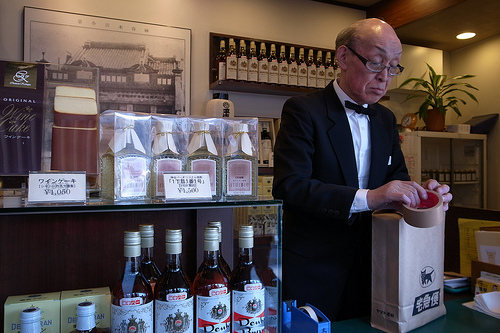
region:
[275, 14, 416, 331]
Old man in a black and white tuxedo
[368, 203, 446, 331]
Brown paper sack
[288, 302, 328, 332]
Blue tape dispenser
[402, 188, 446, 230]
Roll of thick packing tape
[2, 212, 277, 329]
Row of wine bottles on a shelf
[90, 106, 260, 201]
Wine bottles inside of a clear package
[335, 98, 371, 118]
Black bowtie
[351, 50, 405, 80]
Pair of eyeglasses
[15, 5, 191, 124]
Framed photograph on the wall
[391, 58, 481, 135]
Green houseplant on a shelf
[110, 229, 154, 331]
bottle of wine on the bar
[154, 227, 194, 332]
bottle of wine on the bar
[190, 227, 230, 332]
bottle of wine on the bar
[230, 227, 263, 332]
bottle of wine on the bar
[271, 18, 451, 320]
a man wearing a black tuxedo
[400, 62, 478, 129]
a green potted plant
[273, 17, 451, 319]
a man wearing black glasses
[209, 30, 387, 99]
wine bottles on shelf on wall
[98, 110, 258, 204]
liquor bottles on a glass shelf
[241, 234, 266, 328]
There is a bottle of wine here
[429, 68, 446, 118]
There is a plant that is in the corner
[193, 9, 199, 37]
There is a white wall in the background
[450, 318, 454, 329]
There is a countertop here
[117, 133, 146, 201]
There is a liquor that is here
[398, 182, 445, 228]
A roll of tape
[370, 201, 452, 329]
A brown paper bag with a black design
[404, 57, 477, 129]
A green potted house plant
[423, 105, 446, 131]
A brown flower pot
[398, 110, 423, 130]
A small round clock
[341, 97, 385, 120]
A black bow tie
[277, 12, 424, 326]
A man dressed in a black suit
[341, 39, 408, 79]
A black framed pair of glasses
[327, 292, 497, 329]
A green countertop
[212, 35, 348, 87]
A row of bottles on a shelf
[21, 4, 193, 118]
a framed picture on the wall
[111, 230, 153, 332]
a wine bottle on the shelf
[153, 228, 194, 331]
a wine bottle on the shelf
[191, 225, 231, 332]
a wine bottle on the shelf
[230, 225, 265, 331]
a wine bottle on the shelf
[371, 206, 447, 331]
a brown paper package on the bar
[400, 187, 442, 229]
a roll of packing tape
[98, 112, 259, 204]
bottles of liquor on a glass shelf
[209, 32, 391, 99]
liquor bottles on a wooden shelf